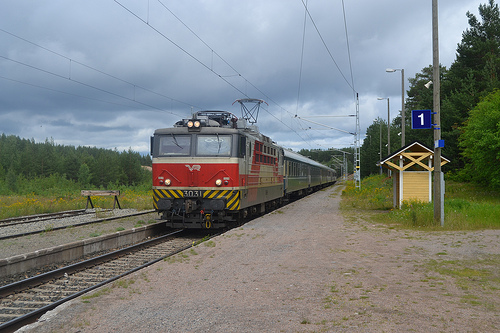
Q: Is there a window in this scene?
A: Yes, there are windows.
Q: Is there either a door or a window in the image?
A: Yes, there are windows.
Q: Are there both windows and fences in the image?
A: No, there are windows but no fences.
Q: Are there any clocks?
A: No, there are no clocks.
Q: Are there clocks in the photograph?
A: No, there are no clocks.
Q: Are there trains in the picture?
A: Yes, there is a train.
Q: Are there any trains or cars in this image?
A: Yes, there is a train.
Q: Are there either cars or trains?
A: Yes, there is a train.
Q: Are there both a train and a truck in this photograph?
A: No, there is a train but no trucks.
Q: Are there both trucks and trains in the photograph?
A: No, there is a train but no trucks.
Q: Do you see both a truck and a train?
A: No, there is a train but no trucks.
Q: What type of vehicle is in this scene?
A: The vehicle is a train.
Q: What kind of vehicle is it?
A: The vehicle is a train.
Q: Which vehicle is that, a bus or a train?
A: This is a train.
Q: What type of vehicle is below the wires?
A: The vehicle is a train.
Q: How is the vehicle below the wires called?
A: The vehicle is a train.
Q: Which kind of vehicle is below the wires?
A: The vehicle is a train.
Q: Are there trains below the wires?
A: Yes, there is a train below the wires.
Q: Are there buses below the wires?
A: No, there is a train below the wires.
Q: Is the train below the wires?
A: Yes, the train is below the wires.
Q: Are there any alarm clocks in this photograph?
A: No, there are no alarm clocks.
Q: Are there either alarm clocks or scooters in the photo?
A: No, there are no alarm clocks or scooters.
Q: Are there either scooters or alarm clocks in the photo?
A: No, there are no alarm clocks or scooters.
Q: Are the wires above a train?
A: Yes, the wires are above a train.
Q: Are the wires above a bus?
A: No, the wires are above a train.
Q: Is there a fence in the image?
A: No, there are no fences.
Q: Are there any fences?
A: No, there are no fences.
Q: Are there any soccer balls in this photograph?
A: No, there are no soccer balls.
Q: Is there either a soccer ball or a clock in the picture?
A: No, there are no soccer balls or clocks.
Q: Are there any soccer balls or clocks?
A: No, there are no soccer balls or clocks.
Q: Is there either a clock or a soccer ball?
A: No, there are no soccer balls or clocks.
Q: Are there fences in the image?
A: No, there are no fences.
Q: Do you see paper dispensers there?
A: No, there are no paper dispensers.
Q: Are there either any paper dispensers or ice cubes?
A: No, there are no paper dispensers or ice cubes.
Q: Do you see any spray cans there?
A: No, there are no spray cans.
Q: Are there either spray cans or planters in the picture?
A: No, there are no spray cans or planters.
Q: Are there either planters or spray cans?
A: No, there are no spray cans or planters.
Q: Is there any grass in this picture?
A: Yes, there is grass.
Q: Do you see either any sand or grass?
A: Yes, there is grass.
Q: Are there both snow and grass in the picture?
A: No, there is grass but no snow.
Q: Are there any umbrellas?
A: No, there are no umbrellas.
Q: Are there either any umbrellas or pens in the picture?
A: No, there are no umbrellas or pens.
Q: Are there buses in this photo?
A: No, there are no buses.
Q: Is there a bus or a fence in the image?
A: No, there are no buses or fences.